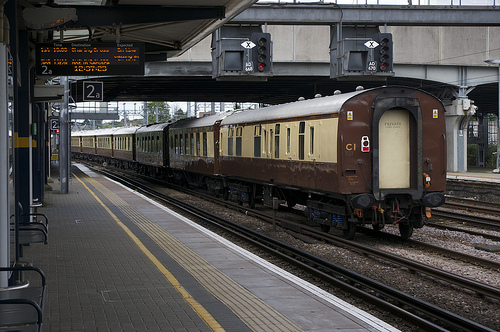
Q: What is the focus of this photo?
A: The train.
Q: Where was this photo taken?
A: A station.